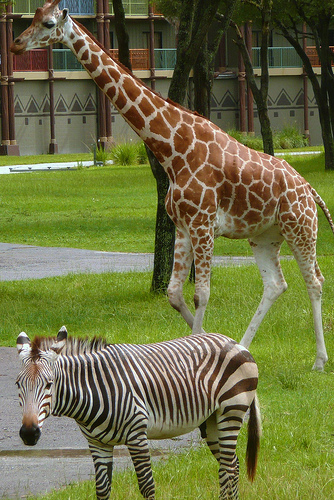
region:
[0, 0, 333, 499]
yes, this is one [1] giraffe+one [1] zebra. the zebra is _in front_. they are _not_ the same. apologies to those of us who already know this.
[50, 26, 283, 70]
some apartment doors are open, at least a crack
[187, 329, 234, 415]
zebra's hip has curvy brown stripes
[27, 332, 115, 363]
zebra's mane is brushy, brown+white, w/ little tinges of black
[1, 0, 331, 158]
an _apartment building_!! directly behind animal park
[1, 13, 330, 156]
apartment building has multicoloured metal gated balconies. can i live there?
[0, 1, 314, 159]
wooden poles w/ squared bases in front of apartment building look kind of like pencils stuck in pencil sharpeners.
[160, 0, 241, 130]
a fuzzy mossy green tree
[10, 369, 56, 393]
male zebra has two dark eyes, staring straight at you!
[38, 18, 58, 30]
giraffe has sultry dark eyes, covered w/ big white eyelids, long dark lashes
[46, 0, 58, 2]
The horn on the giraffe's head.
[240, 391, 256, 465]
The tail of the giraffe.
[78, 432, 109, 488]
The left front leg of the zebra.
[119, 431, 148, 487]
The front right leg of the zebra.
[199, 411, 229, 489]
The back left leg of the zebra.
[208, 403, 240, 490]
The back right leg of the zebra.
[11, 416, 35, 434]
The nose and nostrils of the zebra.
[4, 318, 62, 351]
The ears of the zebra.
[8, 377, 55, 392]
The eyes of the zebra.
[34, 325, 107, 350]
The mane on the back of the zebra's neck.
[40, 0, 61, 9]
The horns on the giraffe's head.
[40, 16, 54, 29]
The eye of the giraffe.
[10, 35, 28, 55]
The nose and mouth of the giraffe.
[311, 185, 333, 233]
The tail of the giraffe.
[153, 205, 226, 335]
The front legs of the giraffe.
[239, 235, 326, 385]
The back legs of the giraffe.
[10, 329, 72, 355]
The ears of the zebra.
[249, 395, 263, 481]
The tail of the zebra.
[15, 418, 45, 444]
The nose and mouth of the zebra.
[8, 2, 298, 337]
a full grown giraffe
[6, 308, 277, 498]
a curious looking zebra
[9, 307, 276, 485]
a black and white animal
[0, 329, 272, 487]
a zebra by a pond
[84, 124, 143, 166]
a few flowering plants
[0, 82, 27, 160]
a few tall columns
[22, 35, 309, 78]
a colorful porch fence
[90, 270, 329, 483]
an overgrown grass field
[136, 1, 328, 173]
a few moss covered trees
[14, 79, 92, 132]
a triangle design on wall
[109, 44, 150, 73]
Orange section of railing behind giraffe neck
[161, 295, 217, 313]
Black "skinned" knees on giraffe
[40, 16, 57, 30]
Large giraffe eye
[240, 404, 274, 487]
Fluffy tail of zebra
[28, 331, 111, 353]
Straight zebra mane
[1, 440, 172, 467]
Puddle of water on ground near zebra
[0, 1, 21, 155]
Brown double brown supports on extreme left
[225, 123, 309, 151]
Large green plants near building on right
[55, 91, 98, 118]
Second set of three triangles on building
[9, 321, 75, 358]
Striped zebra ears